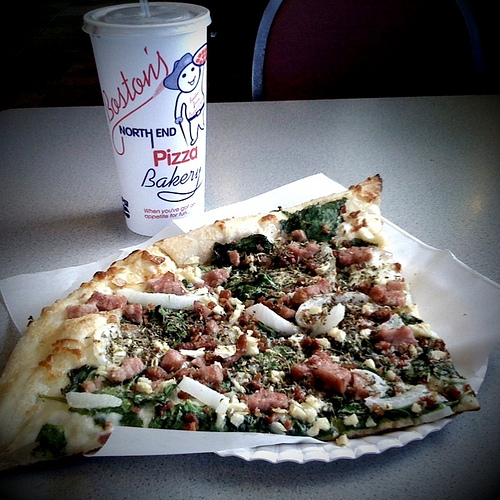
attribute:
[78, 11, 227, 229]
cup — white, on table, sweet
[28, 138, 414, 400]
pizza — on table, tasty, delicious, nice sized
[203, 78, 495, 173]
table — white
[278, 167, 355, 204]
paper — white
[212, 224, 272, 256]
mushroom — on pizza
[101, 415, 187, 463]
napkin — white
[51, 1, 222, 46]
lid — plastic, clear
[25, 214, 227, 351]
crust — packed with cheese, tasty, toasty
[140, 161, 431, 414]
in pizza — flavorful, well seasoned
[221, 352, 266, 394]
cheese — feta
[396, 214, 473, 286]
edge — serrated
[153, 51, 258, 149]
man — on cup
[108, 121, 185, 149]
writing — blue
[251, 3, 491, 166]
chair — red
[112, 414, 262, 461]
paper — wax, white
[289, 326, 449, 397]
meat — delicious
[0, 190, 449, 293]
plate — white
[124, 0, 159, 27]
straw — blue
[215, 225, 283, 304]
herbs — zesty